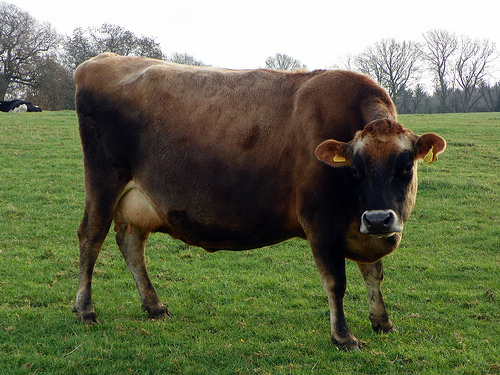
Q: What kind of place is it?
A: It is a field.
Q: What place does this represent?
A: It represents the field.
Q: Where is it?
A: This is at the field.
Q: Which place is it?
A: It is a field.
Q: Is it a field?
A: Yes, it is a field.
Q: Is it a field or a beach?
A: It is a field.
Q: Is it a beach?
A: No, it is a field.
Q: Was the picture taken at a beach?
A: No, the picture was taken in a field.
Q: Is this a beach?
A: No, it is a field.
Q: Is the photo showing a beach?
A: No, the picture is showing a field.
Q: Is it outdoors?
A: Yes, it is outdoors.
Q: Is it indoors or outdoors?
A: It is outdoors.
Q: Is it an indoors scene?
A: No, it is outdoors.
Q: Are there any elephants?
A: No, there are no elephants.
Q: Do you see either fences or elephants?
A: No, there are no elephants or fences.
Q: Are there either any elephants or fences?
A: No, there are no elephants or fences.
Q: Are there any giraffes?
A: No, there are no giraffes.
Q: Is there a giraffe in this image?
A: No, there are no giraffes.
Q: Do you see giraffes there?
A: No, there are no giraffes.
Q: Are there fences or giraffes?
A: No, there are no giraffes or fences.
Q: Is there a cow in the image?
A: Yes, there is a cow.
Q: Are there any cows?
A: Yes, there is a cow.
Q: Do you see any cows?
A: Yes, there is a cow.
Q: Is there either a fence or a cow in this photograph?
A: Yes, there is a cow.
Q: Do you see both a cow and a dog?
A: No, there is a cow but no dogs.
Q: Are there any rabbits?
A: No, there are no rabbits.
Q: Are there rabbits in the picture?
A: No, there are no rabbits.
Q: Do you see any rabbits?
A: No, there are no rabbits.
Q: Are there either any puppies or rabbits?
A: No, there are no rabbits or puppies.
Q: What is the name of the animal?
A: The animal is a cow.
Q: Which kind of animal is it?
A: The animal is a cow.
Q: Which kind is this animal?
A: This is a cow.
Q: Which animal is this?
A: This is a cow.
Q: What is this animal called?
A: This is a cow.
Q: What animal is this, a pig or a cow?
A: This is a cow.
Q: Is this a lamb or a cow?
A: This is a cow.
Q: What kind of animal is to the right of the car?
A: The animal is a cow.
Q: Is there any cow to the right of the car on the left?
A: Yes, there is a cow to the right of the car.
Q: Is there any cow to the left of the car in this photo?
A: No, the cow is to the right of the car.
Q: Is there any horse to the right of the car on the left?
A: No, there is a cow to the right of the car.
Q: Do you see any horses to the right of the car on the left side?
A: No, there is a cow to the right of the car.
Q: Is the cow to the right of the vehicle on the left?
A: Yes, the cow is to the right of the car.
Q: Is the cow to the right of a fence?
A: No, the cow is to the right of the car.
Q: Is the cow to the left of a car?
A: No, the cow is to the right of a car.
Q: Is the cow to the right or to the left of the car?
A: The cow is to the right of the car.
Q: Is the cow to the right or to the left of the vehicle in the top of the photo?
A: The cow is to the right of the car.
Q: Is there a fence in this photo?
A: No, there are no fences.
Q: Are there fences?
A: No, there are no fences.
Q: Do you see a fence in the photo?
A: No, there are no fences.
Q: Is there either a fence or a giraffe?
A: No, there are no fences or giraffes.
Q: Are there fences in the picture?
A: No, there are no fences.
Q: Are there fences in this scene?
A: No, there are no fences.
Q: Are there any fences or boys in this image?
A: No, there are no fences or boys.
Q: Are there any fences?
A: No, there are no fences.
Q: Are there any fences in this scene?
A: No, there are no fences.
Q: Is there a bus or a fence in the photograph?
A: No, there are no fences or buses.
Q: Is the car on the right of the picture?
A: No, the car is on the left of the image.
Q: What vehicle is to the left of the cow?
A: The vehicle is a car.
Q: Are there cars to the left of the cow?
A: Yes, there is a car to the left of the cow.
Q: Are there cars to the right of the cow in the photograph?
A: No, the car is to the left of the cow.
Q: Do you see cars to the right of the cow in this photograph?
A: No, the car is to the left of the cow.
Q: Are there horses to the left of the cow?
A: No, there is a car to the left of the cow.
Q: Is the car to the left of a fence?
A: No, the car is to the left of a cow.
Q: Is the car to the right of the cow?
A: No, the car is to the left of the cow.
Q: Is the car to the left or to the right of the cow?
A: The car is to the left of the cow.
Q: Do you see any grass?
A: Yes, there is grass.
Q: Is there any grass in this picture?
A: Yes, there is grass.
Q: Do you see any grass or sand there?
A: Yes, there is grass.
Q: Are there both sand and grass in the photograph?
A: No, there is grass but no sand.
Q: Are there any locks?
A: No, there are no locks.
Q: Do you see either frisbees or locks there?
A: No, there are no locks or frisbees.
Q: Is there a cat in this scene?
A: No, there are no cats.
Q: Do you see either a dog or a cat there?
A: No, there are no cats or dogs.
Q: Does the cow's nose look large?
A: Yes, the nose is large.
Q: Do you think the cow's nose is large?
A: Yes, the nose is large.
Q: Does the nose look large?
A: Yes, the nose is large.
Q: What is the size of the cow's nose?
A: The nose is large.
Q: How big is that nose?
A: The nose is large.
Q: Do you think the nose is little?
A: No, the nose is large.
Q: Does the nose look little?
A: No, the nose is large.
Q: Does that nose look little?
A: No, the nose is large.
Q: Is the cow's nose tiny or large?
A: The nose is large.